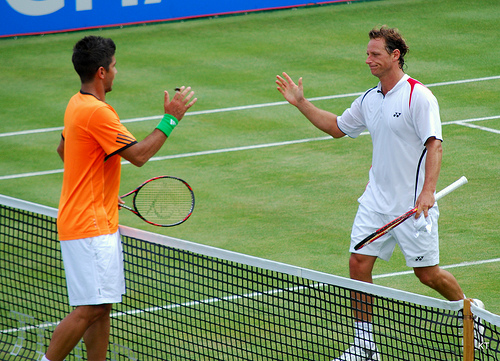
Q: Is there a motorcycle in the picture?
A: No, there are no motorcycles.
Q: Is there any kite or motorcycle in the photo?
A: No, there are no motorcycles or kites.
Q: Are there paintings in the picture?
A: No, there are no paintings.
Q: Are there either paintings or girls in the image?
A: No, there are no paintings or girls.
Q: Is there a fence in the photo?
A: No, there are no fences.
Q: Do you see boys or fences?
A: No, there are no fences or boys.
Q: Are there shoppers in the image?
A: No, there are no shoppers.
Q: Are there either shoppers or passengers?
A: No, there are no shoppers or passengers.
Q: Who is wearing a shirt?
A: The man is wearing a shirt.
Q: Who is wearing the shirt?
A: The man is wearing a shirt.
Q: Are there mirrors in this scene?
A: No, there are no mirrors.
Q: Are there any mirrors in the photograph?
A: No, there are no mirrors.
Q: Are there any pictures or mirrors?
A: No, there are no mirrors or pictures.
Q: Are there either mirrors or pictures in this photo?
A: No, there are no mirrors or pictures.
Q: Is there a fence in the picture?
A: No, there are no fences.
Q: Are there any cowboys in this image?
A: No, there are no cowboys.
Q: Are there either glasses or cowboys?
A: No, there are no cowboys or glasses.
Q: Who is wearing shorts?
A: The man is wearing shorts.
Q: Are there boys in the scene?
A: No, there are no boys.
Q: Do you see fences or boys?
A: No, there are no boys or fences.